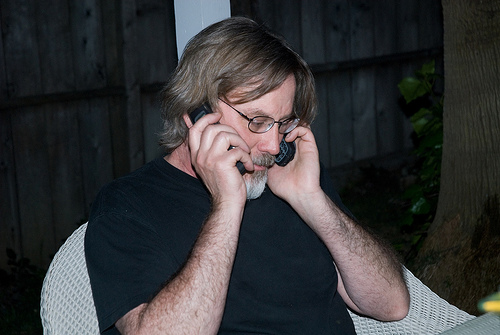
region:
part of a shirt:
[281, 256, 306, 292]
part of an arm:
[366, 284, 372, 295]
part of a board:
[361, 102, 368, 124]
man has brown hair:
[130, 43, 297, 100]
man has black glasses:
[197, 78, 299, 145]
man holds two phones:
[174, 113, 306, 195]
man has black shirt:
[115, 176, 379, 334]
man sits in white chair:
[55, 218, 444, 332]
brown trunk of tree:
[424, 21, 479, 254]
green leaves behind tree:
[385, 55, 460, 235]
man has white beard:
[230, 160, 292, 215]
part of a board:
[393, 115, 405, 137]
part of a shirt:
[283, 257, 295, 274]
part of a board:
[341, 119, 355, 138]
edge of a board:
[107, 139, 134, 171]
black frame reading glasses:
[215, 96, 301, 133]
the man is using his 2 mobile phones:
[85, 18, 409, 334]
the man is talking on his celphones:
[83, 18, 407, 334]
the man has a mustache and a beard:
[250, 152, 274, 206]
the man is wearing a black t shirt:
[86, 17, 403, 334]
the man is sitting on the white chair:
[40, 15, 485, 330]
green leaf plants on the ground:
[390, 59, 440, 248]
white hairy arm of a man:
[295, 128, 412, 320]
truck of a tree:
[403, 0, 498, 319]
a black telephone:
[191, 106, 209, 120]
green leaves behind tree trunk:
[383, 51, 457, 256]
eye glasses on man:
[211, 85, 303, 143]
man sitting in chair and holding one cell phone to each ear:
[36, 12, 476, 334]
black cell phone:
[183, 98, 248, 177]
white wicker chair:
[35, 215, 480, 333]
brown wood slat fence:
[1, 1, 441, 272]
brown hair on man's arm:
[328, 193, 403, 292]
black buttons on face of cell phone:
[275, 135, 290, 164]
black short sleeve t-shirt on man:
[80, 152, 362, 334]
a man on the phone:
[22, 18, 491, 333]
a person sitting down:
[45, 13, 475, 333]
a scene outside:
[3, 4, 473, 334]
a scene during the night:
[7, 3, 488, 333]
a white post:
[158, 0, 258, 189]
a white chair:
[16, 175, 483, 333]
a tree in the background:
[416, 11, 498, 279]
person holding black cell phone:
[187, 98, 244, 175]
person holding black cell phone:
[272, 133, 295, 169]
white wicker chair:
[39, 200, 474, 333]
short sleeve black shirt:
[91, 161, 358, 328]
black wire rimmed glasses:
[222, 93, 298, 134]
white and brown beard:
[237, 140, 282, 223]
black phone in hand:
[190, 83, 250, 198]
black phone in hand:
[270, 107, 317, 185]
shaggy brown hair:
[154, 10, 305, 205]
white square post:
[174, 4, 236, 88]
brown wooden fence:
[3, 4, 470, 251]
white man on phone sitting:
[84, 16, 411, 334]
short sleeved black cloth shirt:
[84, 155, 359, 334]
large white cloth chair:
[39, 215, 480, 334]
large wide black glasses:
[222, 101, 303, 133]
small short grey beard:
[241, 176, 266, 198]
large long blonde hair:
[149, 16, 317, 150]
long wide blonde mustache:
[249, 154, 274, 168]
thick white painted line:
[175, 0, 234, 66]